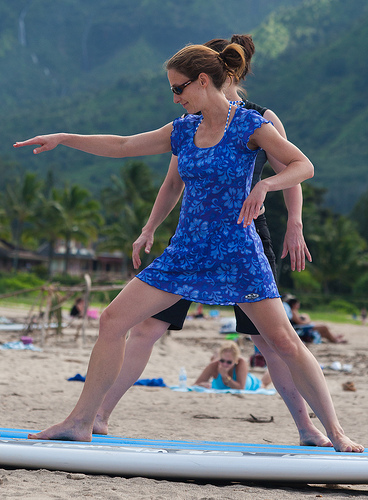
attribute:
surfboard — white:
[0, 437, 368, 486]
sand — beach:
[3, 304, 367, 499]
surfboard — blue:
[2, 424, 367, 457]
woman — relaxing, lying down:
[195, 343, 273, 391]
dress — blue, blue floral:
[129, 105, 285, 304]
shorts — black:
[147, 211, 279, 333]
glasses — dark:
[169, 73, 198, 98]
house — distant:
[3, 235, 46, 272]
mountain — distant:
[2, 1, 367, 216]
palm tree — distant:
[46, 179, 100, 280]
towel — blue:
[65, 371, 166, 388]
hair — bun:
[162, 43, 246, 84]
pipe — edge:
[248, 413, 276, 425]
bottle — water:
[176, 363, 188, 391]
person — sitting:
[287, 294, 351, 346]